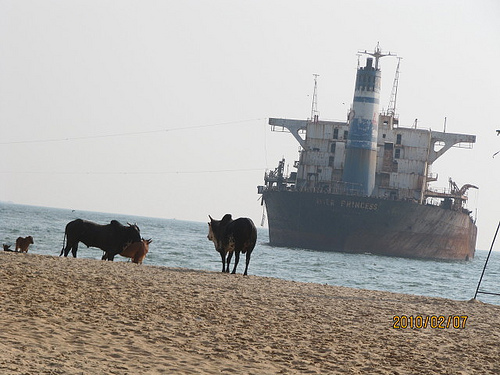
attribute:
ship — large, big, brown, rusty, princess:
[258, 45, 478, 262]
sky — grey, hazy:
[2, 1, 254, 204]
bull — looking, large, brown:
[209, 212, 258, 276]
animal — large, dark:
[60, 214, 155, 268]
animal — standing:
[11, 233, 39, 253]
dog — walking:
[1, 241, 13, 252]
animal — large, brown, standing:
[119, 237, 156, 264]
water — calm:
[291, 261, 458, 282]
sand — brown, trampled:
[137, 315, 319, 352]